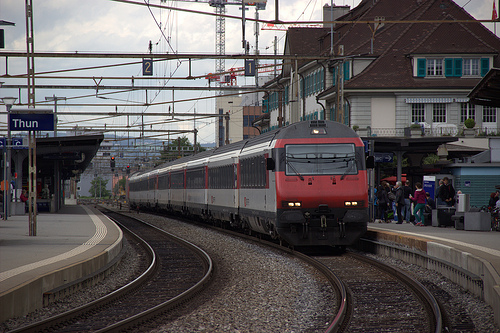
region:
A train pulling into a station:
[110, 108, 388, 268]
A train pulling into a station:
[117, 108, 399, 273]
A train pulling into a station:
[115, 111, 385, 272]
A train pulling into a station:
[104, 108, 391, 265]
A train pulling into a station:
[120, 111, 394, 262]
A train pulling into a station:
[105, 112, 380, 270]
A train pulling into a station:
[115, 111, 387, 258]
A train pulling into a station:
[108, 108, 380, 265]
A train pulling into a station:
[109, 105, 394, 261]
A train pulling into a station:
[119, 111, 390, 266]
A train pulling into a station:
[115, 117, 393, 259]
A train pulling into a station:
[119, 112, 386, 258]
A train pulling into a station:
[119, 114, 382, 259]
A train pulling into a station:
[119, 116, 387, 259]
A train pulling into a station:
[114, 111, 383, 261]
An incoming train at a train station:
[110, 111, 393, 252]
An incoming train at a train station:
[120, 117, 403, 257]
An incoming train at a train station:
[110, 109, 405, 266]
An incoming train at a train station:
[115, 115, 395, 267]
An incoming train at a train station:
[115, 112, 385, 264]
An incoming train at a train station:
[121, 113, 385, 268]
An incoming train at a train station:
[121, 108, 391, 269]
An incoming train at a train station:
[121, 113, 393, 260]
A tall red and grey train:
[119, 128, 351, 267]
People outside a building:
[406, 185, 425, 225]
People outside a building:
[431, 168, 463, 213]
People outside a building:
[375, 164, 409, 210]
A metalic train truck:
[295, 238, 445, 330]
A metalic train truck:
[102, 271, 202, 329]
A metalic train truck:
[115, 192, 178, 258]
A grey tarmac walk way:
[43, 189, 107, 256]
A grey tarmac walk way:
[5, 225, 47, 275]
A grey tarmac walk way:
[36, 200, 98, 230]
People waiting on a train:
[370, 173, 457, 229]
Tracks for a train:
[306, 255, 441, 331]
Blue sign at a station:
[8, 110, 58, 135]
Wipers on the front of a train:
[278, 140, 364, 181]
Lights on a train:
[278, 196, 303, 211]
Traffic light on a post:
[101, 152, 122, 176]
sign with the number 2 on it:
[143, 57, 153, 74]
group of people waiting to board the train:
[381, 177, 449, 232]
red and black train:
[274, 125, 371, 230]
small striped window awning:
[405, 97, 470, 102]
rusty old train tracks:
[329, 254, 415, 324]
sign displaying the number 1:
[244, 58, 255, 74]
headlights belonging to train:
[284, 199, 360, 208]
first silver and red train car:
[206, 149, 238, 215]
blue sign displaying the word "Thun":
[8, 112, 51, 129]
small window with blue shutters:
[416, 56, 491, 76]